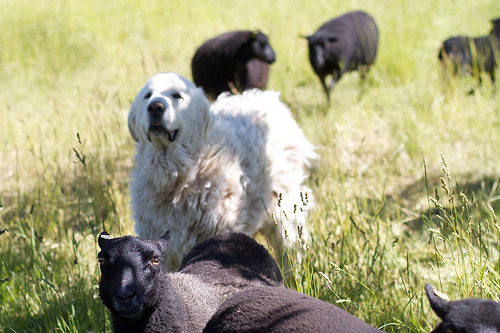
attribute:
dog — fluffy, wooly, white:
[126, 72, 319, 293]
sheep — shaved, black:
[189, 28, 276, 91]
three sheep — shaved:
[188, 9, 500, 99]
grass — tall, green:
[1, 0, 500, 332]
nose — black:
[146, 97, 169, 125]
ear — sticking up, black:
[423, 284, 448, 318]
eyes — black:
[139, 89, 183, 102]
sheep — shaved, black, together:
[96, 233, 499, 327]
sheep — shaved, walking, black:
[299, 12, 381, 113]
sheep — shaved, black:
[97, 236, 283, 332]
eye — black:
[170, 91, 185, 105]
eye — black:
[144, 89, 155, 101]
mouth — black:
[145, 119, 181, 146]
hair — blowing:
[148, 111, 298, 240]